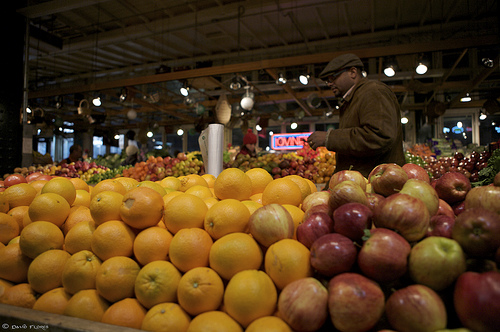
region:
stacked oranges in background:
[117, 196, 289, 317]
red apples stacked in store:
[326, 218, 468, 325]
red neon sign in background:
[248, 118, 354, 177]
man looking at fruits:
[297, 61, 475, 196]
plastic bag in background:
[187, 118, 259, 183]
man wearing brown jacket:
[312, 56, 417, 161]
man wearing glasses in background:
[302, 41, 454, 171]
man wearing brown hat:
[307, 35, 431, 92]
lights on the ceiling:
[69, 63, 324, 112]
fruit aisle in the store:
[29, 35, 459, 317]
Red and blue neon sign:
[271, 132, 318, 147]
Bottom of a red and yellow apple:
[410, 235, 465, 280]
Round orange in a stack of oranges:
[177, 262, 225, 312]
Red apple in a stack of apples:
[330, 200, 375, 235]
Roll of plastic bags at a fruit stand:
[196, 117, 226, 177]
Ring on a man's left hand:
[306, 138, 317, 145]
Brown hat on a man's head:
[312, 53, 367, 78]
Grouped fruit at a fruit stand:
[11, 146, 217, 177]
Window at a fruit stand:
[433, 110, 479, 151]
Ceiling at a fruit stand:
[30, 1, 499, 63]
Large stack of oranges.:
[0, 166, 318, 330]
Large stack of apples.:
[280, 162, 496, 330]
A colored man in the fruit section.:
[303, 51, 408, 168]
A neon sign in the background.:
[269, 129, 314, 151]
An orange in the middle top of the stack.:
[116, 186, 165, 229]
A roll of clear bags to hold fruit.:
[194, 121, 227, 176]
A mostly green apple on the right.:
[409, 231, 467, 283]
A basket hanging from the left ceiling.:
[74, 97, 91, 117]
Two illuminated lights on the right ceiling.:
[380, 60, 430, 78]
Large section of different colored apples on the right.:
[402, 151, 494, 177]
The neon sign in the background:
[268, 128, 315, 148]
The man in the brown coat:
[304, 50, 406, 175]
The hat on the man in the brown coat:
[316, 48, 364, 83]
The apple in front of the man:
[278, 160, 499, 330]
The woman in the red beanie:
[235, 124, 259, 161]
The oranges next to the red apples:
[0, 169, 315, 330]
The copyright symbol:
[0, 317, 9, 330]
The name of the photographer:
[9, 318, 53, 330]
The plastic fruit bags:
[194, 117, 229, 180]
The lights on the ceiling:
[17, 61, 492, 146]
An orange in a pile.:
[198, 192, 250, 242]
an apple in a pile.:
[349, 225, 416, 285]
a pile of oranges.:
[0, 162, 332, 329]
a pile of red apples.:
[293, 161, 498, 330]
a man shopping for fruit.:
[300, 40, 412, 182]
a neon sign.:
[258, 121, 335, 152]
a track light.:
[409, 51, 441, 81]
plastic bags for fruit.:
[188, 100, 239, 192]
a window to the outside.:
[107, 128, 135, 153]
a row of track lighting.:
[17, 53, 442, 125]